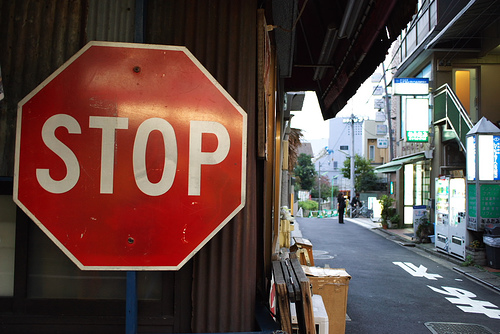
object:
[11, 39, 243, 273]
sign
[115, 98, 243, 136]
reflection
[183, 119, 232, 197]
p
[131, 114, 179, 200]
o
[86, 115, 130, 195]
t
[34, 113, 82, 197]
s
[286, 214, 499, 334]
pavement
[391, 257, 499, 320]
writing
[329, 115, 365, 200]
building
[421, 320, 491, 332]
cover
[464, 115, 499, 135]
pyramid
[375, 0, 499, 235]
building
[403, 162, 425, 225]
light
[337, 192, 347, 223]
person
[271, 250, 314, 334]
wood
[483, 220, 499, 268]
trash can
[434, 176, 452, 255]
vending machine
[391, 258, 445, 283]
symbol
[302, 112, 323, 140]
sky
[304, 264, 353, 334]
box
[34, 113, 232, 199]
letters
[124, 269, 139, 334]
pole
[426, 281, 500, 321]
marking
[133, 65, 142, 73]
screw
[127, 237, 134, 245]
screw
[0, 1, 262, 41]
wall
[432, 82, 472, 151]
stairs